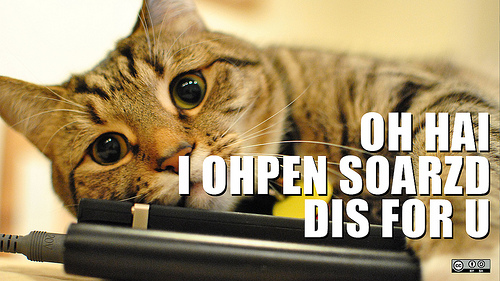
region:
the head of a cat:
[1, 4, 288, 223]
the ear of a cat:
[0, 70, 60, 160]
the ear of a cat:
[131, 0, 216, 38]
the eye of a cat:
[160, 61, 222, 119]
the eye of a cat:
[82, 123, 137, 173]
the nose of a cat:
[146, 126, 203, 179]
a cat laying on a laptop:
[1, 4, 493, 251]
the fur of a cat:
[274, 61, 347, 148]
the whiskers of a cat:
[224, 70, 356, 153]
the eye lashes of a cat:
[26, 80, 93, 137]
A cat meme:
[3, 3, 496, 278]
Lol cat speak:
[174, 108, 492, 240]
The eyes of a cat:
[76, 63, 216, 170]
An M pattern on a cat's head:
[70, 38, 167, 127]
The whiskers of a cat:
[207, 91, 342, 153]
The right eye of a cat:
[78, 121, 141, 172]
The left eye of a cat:
[163, 62, 214, 114]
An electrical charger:
[2, 223, 69, 268]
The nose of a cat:
[149, 126, 197, 176]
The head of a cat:
[3, 3, 269, 214]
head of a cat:
[7, 15, 277, 209]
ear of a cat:
[0, 60, 65, 126]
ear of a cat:
[132, 0, 225, 54]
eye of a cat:
[85, 118, 135, 175]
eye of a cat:
[172, 48, 225, 103]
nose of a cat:
[145, 133, 200, 189]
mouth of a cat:
[155, 144, 232, 216]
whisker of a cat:
[238, 85, 321, 173]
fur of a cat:
[330, 65, 412, 125]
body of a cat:
[275, 43, 495, 225]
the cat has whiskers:
[51, 89, 328, 221]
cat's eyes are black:
[38, 53, 255, 208]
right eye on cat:
[82, 122, 139, 172]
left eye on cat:
[167, 68, 217, 123]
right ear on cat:
[5, 71, 60, 150]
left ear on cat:
[129, 2, 221, 34]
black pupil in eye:
[88, 131, 124, 165]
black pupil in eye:
[174, 68, 214, 110]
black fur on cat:
[68, 70, 108, 102]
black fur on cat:
[117, 26, 145, 92]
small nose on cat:
[162, 143, 213, 178]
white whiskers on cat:
[225, 91, 342, 160]